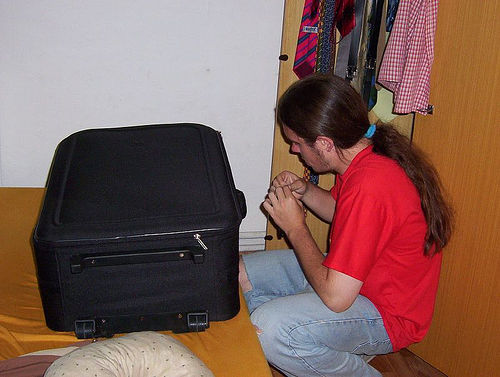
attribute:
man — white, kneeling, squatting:
[279, 84, 412, 353]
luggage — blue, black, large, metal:
[66, 123, 241, 330]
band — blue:
[358, 112, 381, 140]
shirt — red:
[335, 166, 437, 305]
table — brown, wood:
[13, 275, 45, 320]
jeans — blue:
[279, 282, 312, 327]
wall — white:
[147, 14, 233, 67]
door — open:
[447, 19, 487, 62]